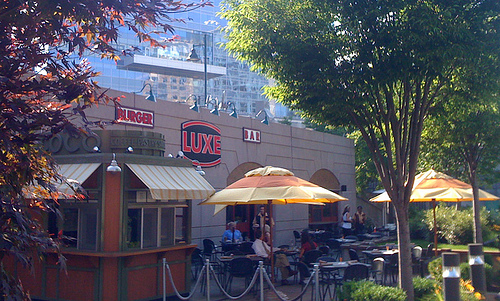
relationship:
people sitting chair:
[243, 222, 339, 279] [247, 252, 272, 286]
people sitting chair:
[243, 222, 339, 279] [301, 246, 323, 288]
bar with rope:
[156, 253, 174, 299] [163, 258, 207, 298]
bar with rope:
[199, 253, 219, 299] [208, 260, 260, 299]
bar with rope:
[255, 254, 272, 298] [262, 267, 314, 296]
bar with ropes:
[162, 257, 167, 300] [161, 256, 211, 299]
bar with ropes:
[258, 260, 265, 301] [259, 260, 311, 300]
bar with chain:
[258, 260, 265, 301] [163, 264, 315, 301]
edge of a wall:
[311, 165, 344, 186] [38, 86, 355, 237]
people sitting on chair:
[249, 225, 344, 282] [240, 243, 267, 273]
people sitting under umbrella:
[250, 227, 320, 287] [197, 162, 349, 292]